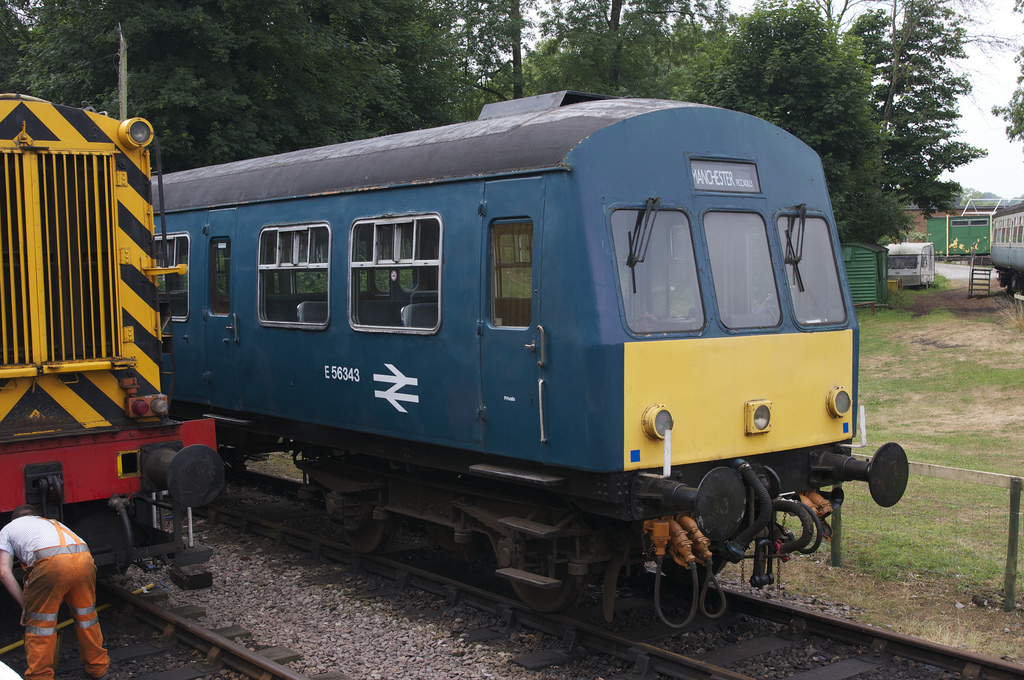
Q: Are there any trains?
A: Yes, there is a train.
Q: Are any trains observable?
A: Yes, there is a train.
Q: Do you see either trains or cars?
A: Yes, there is a train.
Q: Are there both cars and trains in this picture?
A: No, there is a train but no cars.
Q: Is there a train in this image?
A: Yes, there is a train.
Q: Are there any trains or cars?
A: Yes, there is a train.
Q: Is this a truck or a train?
A: This is a train.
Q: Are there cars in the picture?
A: No, there are no cars.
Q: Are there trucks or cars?
A: No, there are no cars or trucks.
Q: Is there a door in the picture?
A: Yes, there is a door.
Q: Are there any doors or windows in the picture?
A: Yes, there is a door.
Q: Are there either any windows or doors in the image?
A: Yes, there is a door.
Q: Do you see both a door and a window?
A: Yes, there are both a door and a window.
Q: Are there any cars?
A: No, there are no cars.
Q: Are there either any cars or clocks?
A: No, there are no cars or clocks.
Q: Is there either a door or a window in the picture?
A: Yes, there is a window.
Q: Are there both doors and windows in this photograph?
A: Yes, there are both a window and a door.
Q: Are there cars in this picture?
A: No, there are no cars.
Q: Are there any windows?
A: Yes, there is a window.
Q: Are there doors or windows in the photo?
A: Yes, there is a window.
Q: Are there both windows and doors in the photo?
A: Yes, there are both a window and doors.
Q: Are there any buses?
A: No, there are no buses.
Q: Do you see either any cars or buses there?
A: No, there are no buses or cars.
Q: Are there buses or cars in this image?
A: No, there are no buses or cars.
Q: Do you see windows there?
A: Yes, there is a window.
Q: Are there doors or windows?
A: Yes, there is a window.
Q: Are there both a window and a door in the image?
A: Yes, there are both a window and a door.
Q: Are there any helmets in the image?
A: No, there are no helmets.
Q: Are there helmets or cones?
A: No, there are no helmets or cones.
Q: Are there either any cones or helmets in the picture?
A: No, there are no helmets or cones.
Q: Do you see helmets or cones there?
A: No, there are no helmets or cones.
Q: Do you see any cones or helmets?
A: No, there are no helmets or cones.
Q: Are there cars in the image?
A: No, there are no cars.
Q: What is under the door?
A: The step is under the door.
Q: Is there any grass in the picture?
A: Yes, there is grass.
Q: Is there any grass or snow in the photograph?
A: Yes, there is grass.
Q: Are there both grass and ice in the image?
A: No, there is grass but no ice.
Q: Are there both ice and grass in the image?
A: No, there is grass but no ice.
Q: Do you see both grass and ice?
A: No, there is grass but no ice.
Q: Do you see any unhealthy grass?
A: Yes, there is unhealthy grass.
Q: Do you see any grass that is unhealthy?
A: Yes, there is grass that is unhealthy.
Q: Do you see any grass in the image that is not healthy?
A: Yes, there is unhealthy grass.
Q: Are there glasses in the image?
A: No, there are no glasses.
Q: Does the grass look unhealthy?
A: Yes, the grass is unhealthy.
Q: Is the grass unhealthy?
A: Yes, the grass is unhealthy.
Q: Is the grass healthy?
A: No, the grass is unhealthy.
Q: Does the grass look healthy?
A: No, the grass is unhealthy.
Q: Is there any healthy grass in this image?
A: No, there is grass but it is unhealthy.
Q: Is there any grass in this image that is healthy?
A: No, there is grass but it is unhealthy.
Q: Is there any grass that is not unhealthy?
A: No, there is grass but it is unhealthy.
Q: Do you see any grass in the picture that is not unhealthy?
A: No, there is grass but it is unhealthy.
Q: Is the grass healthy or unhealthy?
A: The grass is unhealthy.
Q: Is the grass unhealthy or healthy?
A: The grass is unhealthy.